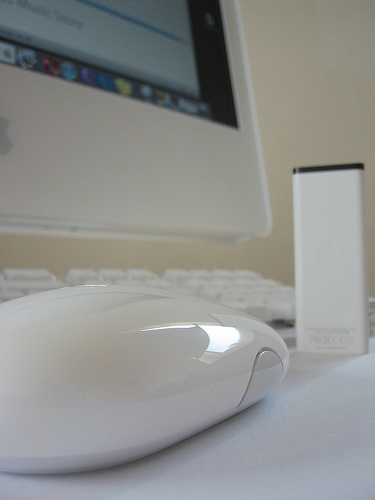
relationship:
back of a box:
[296, 167, 361, 345] [292, 163, 368, 355]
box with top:
[292, 163, 368, 355] [285, 153, 362, 175]